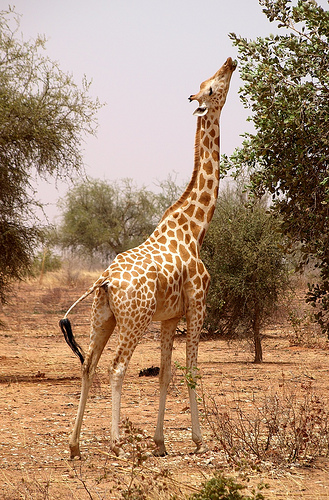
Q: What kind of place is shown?
A: It is a field.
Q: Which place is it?
A: It is a field.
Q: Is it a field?
A: Yes, it is a field.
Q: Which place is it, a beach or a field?
A: It is a field.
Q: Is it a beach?
A: No, it is a field.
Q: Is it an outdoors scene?
A: Yes, it is outdoors.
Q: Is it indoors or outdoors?
A: It is outdoors.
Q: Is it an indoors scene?
A: No, it is outdoors.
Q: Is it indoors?
A: No, it is outdoors.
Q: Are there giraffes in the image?
A: Yes, there is a giraffe.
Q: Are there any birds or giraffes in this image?
A: Yes, there is a giraffe.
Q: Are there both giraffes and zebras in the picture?
A: No, there is a giraffe but no zebras.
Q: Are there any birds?
A: No, there are no birds.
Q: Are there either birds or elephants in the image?
A: No, there are no birds or elephants.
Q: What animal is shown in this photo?
A: The animal is a giraffe.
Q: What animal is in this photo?
A: The animal is a giraffe.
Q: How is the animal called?
A: The animal is a giraffe.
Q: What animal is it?
A: The animal is a giraffe.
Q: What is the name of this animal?
A: This is a giraffe.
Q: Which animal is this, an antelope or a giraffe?
A: This is a giraffe.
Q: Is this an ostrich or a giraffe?
A: This is a giraffe.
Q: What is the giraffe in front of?
A: The giraffe is in front of the trees.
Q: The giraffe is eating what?
A: The giraffe is eating leaves.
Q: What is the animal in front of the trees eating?
A: The giraffe is eating leaves.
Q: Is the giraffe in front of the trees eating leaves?
A: Yes, the giraffe is eating leaves.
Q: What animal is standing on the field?
A: The giraffe is standing on the field.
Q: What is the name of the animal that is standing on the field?
A: The animal is a giraffe.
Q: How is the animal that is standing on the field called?
A: The animal is a giraffe.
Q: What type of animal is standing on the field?
A: The animal is a giraffe.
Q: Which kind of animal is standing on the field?
A: The animal is a giraffe.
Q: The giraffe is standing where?
A: The giraffe is standing on the field.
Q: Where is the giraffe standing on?
A: The giraffe is standing on the field.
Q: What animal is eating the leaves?
A: The giraffe is eating the leaves.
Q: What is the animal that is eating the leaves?
A: The animal is a giraffe.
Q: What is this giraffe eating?
A: The giraffe is eating leaves.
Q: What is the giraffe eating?
A: The giraffe is eating leaves.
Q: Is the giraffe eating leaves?
A: Yes, the giraffe is eating leaves.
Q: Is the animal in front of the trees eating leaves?
A: Yes, the giraffe is eating leaves.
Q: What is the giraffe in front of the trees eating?
A: The giraffe is eating leaves.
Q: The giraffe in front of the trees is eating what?
A: The giraffe is eating leaves.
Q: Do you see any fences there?
A: No, there are no fences.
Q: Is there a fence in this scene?
A: No, there are no fences.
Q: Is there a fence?
A: No, there are no fences.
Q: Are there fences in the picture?
A: No, there are no fences.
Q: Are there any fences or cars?
A: No, there are no fences or cars.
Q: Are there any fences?
A: No, there are no fences.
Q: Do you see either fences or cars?
A: No, there are no fences or cars.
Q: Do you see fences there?
A: No, there are no fences.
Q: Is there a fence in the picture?
A: No, there are no fences.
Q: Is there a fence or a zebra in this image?
A: No, there are no fences or zebras.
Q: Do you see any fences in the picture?
A: No, there are no fences.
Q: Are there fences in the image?
A: No, there are no fences.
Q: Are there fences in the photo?
A: No, there are no fences.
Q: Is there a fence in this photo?
A: No, there are no fences.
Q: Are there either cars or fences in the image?
A: No, there are no fences or cars.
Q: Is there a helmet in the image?
A: No, there are no helmets.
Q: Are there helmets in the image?
A: No, there are no helmets.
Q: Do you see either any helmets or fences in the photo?
A: No, there are no helmets or fences.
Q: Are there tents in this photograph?
A: No, there are no tents.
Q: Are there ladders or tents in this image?
A: No, there are no tents or ladders.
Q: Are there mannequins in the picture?
A: No, there are no mannequins.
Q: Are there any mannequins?
A: No, there are no mannequins.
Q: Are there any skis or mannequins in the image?
A: No, there are no mannequins or skis.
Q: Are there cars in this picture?
A: No, there are no cars.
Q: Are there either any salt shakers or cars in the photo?
A: No, there are no cars or salt shakers.